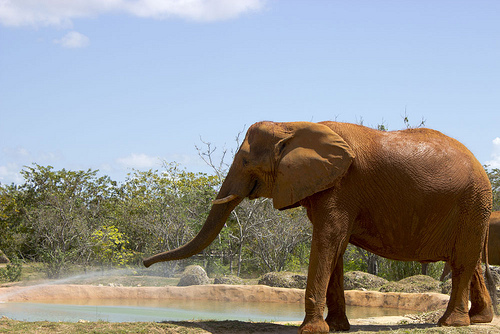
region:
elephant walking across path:
[140, 115, 495, 332]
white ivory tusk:
[207, 188, 239, 205]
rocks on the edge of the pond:
[174, 262, 304, 286]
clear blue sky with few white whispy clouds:
[0, 5, 499, 112]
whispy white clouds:
[111, 147, 162, 168]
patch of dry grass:
[3, 317, 281, 330]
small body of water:
[2, 295, 428, 318]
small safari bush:
[25, 182, 100, 278]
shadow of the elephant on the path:
[155, 311, 295, 327]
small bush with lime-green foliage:
[82, 220, 132, 262]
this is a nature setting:
[26, 32, 476, 328]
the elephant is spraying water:
[31, 88, 416, 315]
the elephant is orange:
[232, 100, 482, 291]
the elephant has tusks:
[194, 193, 251, 216]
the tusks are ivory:
[184, 191, 232, 208]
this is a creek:
[51, 294, 180, 333]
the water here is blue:
[81, 300, 178, 332]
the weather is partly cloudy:
[22, 16, 240, 129]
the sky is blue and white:
[43, 19, 162, 114]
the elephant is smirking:
[231, 158, 278, 202]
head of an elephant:
[195, 86, 309, 248]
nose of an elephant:
[100, 238, 234, 298]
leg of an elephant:
[293, 221, 338, 325]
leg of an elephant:
[322, 253, 370, 323]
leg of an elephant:
[440, 256, 480, 331]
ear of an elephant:
[256, 118, 376, 223]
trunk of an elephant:
[200, 191, 264, 215]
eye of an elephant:
[223, 141, 271, 168]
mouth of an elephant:
[233, 176, 273, 203]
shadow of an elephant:
[207, 301, 285, 331]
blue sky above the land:
[61, 45, 203, 140]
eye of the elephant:
[229, 147, 260, 177]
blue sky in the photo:
[191, 40, 341, 105]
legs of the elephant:
[291, 241, 496, 321]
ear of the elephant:
[241, 112, 361, 232]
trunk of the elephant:
[105, 167, 247, 282]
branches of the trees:
[32, 175, 162, 255]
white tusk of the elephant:
[195, 182, 255, 212]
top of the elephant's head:
[226, 107, 281, 153]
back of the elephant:
[428, 143, 493, 263]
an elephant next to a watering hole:
[134, 117, 499, 332]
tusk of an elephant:
[201, 180, 241, 206]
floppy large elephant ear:
[269, 123, 358, 209]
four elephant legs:
[293, 215, 498, 332]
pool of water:
[3, 293, 451, 325]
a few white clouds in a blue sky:
[1, 4, 498, 201]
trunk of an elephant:
[138, 169, 258, 278]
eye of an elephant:
[238, 151, 251, 170]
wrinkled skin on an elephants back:
[345, 120, 496, 242]